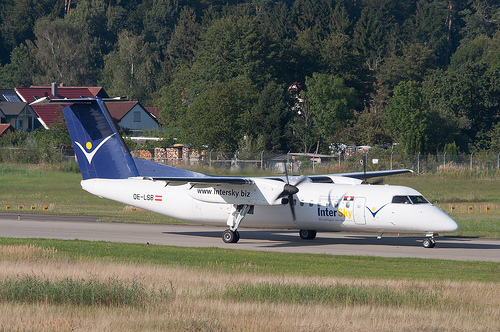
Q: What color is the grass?
A: Green and brown.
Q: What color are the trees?
A: Green.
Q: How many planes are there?
A: One.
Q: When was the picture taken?
A: Daytime.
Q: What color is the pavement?
A: Gray.